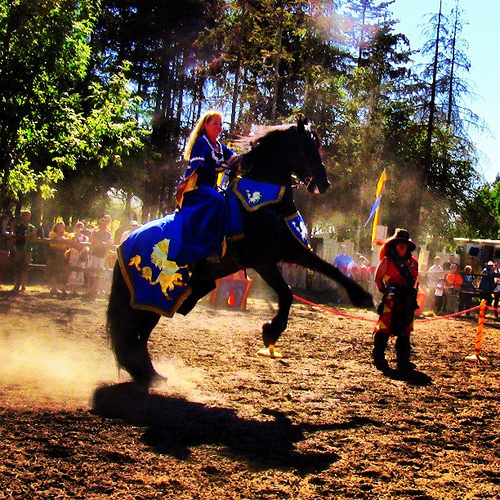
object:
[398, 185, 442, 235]
dust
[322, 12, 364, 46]
dust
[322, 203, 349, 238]
dust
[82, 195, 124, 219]
dust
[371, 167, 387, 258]
pole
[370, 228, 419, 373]
man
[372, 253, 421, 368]
costume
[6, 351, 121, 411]
ground dust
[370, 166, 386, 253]
iron rod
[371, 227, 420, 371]
girl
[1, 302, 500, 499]
ground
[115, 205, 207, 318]
cloth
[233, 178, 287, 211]
cloth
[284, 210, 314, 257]
cloth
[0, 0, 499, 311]
trees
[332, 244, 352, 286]
person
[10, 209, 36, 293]
person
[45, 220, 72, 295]
person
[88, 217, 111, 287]
person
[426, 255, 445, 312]
person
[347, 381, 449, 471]
hoof prints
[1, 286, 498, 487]
dirt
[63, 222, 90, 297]
person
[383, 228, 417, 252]
hat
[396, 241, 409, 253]
head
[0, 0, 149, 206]
leaves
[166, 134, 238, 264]
costume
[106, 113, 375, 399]
black horse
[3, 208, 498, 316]
spectators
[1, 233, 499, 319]
fence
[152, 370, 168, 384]
horse's feet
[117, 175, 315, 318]
clothing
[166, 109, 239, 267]
girl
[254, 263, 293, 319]
leg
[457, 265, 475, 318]
person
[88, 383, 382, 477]
shadow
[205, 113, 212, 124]
headband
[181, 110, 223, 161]
hair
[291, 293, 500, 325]
rope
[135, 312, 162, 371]
leg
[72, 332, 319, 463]
sand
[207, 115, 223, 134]
face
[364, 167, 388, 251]
flag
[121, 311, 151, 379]
legs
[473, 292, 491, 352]
pole